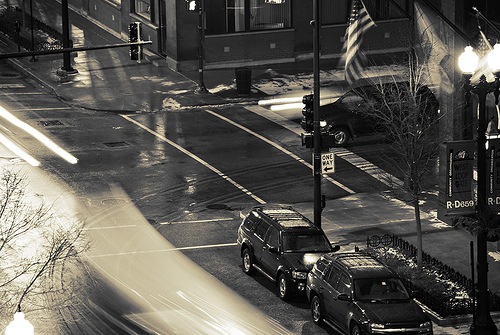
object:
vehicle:
[237, 205, 340, 301]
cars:
[236, 203, 437, 333]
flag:
[337, 2, 379, 88]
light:
[127, 23, 144, 61]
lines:
[124, 118, 195, 164]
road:
[56, 83, 252, 217]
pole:
[20, 48, 71, 63]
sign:
[321, 152, 335, 174]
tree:
[368, 74, 441, 268]